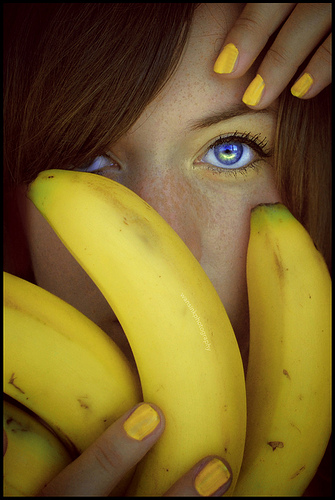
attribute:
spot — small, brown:
[267, 438, 289, 455]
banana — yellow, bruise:
[245, 206, 322, 499]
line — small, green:
[269, 246, 294, 292]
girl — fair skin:
[215, 34, 240, 75]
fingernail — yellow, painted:
[209, 52, 232, 81]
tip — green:
[252, 199, 288, 216]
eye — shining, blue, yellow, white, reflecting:
[200, 147, 266, 172]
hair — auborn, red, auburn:
[5, 6, 334, 259]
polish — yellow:
[240, 82, 263, 99]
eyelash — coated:
[212, 133, 271, 161]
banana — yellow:
[37, 179, 236, 499]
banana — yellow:
[5, 278, 124, 469]